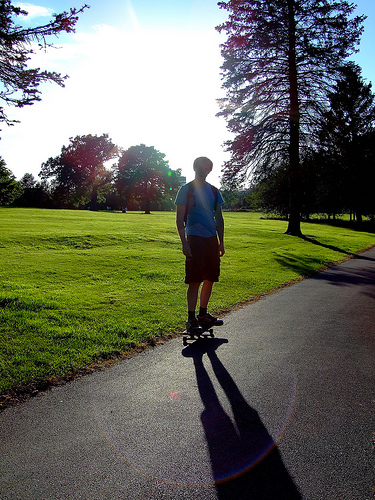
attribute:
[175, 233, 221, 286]
shorts — dark, brown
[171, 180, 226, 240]
shirt — blue, light blue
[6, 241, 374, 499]
path — asphalt, black, paved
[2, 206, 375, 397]
grass — green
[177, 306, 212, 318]
socks — low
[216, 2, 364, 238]
tree — large, tall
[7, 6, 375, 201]
sky — blue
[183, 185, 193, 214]
straps — dark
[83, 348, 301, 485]
light — rainbow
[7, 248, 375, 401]
edge — brown